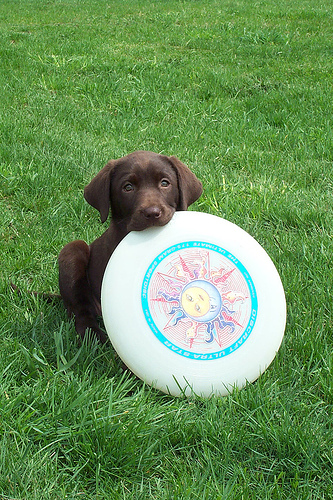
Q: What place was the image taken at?
A: It was taken at the field.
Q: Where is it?
A: This is at the field.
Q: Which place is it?
A: It is a field.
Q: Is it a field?
A: Yes, it is a field.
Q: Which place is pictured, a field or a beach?
A: It is a field.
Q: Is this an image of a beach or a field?
A: It is showing a field.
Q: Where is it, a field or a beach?
A: It is a field.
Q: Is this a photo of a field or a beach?
A: It is showing a field.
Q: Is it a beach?
A: No, it is a field.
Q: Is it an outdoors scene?
A: Yes, it is outdoors.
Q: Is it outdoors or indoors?
A: It is outdoors.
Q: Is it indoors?
A: No, it is outdoors.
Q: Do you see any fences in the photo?
A: No, there are no fences.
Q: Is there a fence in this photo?
A: No, there are no fences.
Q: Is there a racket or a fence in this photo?
A: No, there are no fences or rackets.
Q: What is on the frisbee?
A: The logo is on the frisbee.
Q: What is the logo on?
A: The logo is on the frisbee.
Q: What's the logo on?
A: The logo is on the frisbee.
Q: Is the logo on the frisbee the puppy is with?
A: Yes, the logo is on the frisbee.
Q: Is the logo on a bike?
A: No, the logo is on the frisbee.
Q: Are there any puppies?
A: Yes, there is a puppy.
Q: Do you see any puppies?
A: Yes, there is a puppy.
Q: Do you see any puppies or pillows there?
A: Yes, there is a puppy.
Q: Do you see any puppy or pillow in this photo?
A: Yes, there is a puppy.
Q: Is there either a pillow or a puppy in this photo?
A: Yes, there is a puppy.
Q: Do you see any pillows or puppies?
A: Yes, there is a puppy.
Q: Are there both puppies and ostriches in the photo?
A: No, there is a puppy but no ostriches.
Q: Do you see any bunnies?
A: No, there are no bunnies.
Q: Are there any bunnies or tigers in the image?
A: No, there are no bunnies or tigers.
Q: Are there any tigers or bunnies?
A: No, there are no bunnies or tigers.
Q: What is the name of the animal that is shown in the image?
A: The animal is a puppy.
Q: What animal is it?
A: The animal is a puppy.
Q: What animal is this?
A: This is a puppy.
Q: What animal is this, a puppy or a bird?
A: This is a puppy.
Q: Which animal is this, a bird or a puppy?
A: This is a puppy.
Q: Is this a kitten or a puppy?
A: This is a puppy.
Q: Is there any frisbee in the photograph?
A: Yes, there is a frisbee.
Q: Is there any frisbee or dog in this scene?
A: Yes, there is a frisbee.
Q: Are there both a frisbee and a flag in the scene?
A: No, there is a frisbee but no flags.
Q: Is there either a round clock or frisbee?
A: Yes, there is a round frisbee.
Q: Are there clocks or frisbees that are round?
A: Yes, the frisbee is round.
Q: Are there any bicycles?
A: No, there are no bicycles.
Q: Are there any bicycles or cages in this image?
A: No, there are no bicycles or cages.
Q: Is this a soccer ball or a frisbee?
A: This is a frisbee.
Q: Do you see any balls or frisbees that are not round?
A: No, there is a frisbee but it is round.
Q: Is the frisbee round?
A: Yes, the frisbee is round.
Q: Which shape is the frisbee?
A: The frisbee is round.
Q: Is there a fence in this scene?
A: No, there are no fences.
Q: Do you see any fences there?
A: No, there are no fences.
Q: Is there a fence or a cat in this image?
A: No, there are no fences or cats.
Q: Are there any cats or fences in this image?
A: No, there are no fences or cats.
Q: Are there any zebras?
A: No, there are no zebras.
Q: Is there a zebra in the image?
A: No, there are no zebras.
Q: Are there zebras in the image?
A: No, there are no zebras.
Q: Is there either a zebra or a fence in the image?
A: No, there are no zebras or fences.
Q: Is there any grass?
A: Yes, there is grass.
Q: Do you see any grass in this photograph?
A: Yes, there is grass.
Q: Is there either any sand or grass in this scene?
A: Yes, there is grass.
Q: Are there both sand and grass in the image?
A: No, there is grass but no sand.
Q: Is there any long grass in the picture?
A: Yes, there is long grass.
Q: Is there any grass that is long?
A: Yes, there is grass that is long.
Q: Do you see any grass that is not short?
A: Yes, there is long grass.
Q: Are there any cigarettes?
A: No, there are no cigarettes.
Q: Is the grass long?
A: Yes, the grass is long.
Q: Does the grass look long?
A: Yes, the grass is long.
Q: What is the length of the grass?
A: The grass is long.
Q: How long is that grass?
A: The grass is long.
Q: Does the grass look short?
A: No, the grass is long.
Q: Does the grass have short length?
A: No, the grass is long.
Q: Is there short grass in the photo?
A: No, there is grass but it is long.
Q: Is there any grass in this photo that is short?
A: No, there is grass but it is long.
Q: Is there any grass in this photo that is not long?
A: No, there is grass but it is long.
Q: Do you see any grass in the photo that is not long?
A: No, there is grass but it is long.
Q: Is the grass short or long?
A: The grass is long.